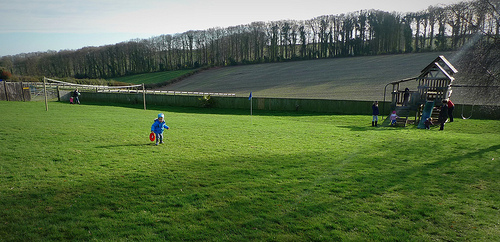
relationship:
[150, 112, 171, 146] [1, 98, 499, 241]
children on grass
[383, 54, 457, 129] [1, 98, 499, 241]
playground on grass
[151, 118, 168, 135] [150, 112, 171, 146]
jacket on children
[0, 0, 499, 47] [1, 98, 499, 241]
sky above grass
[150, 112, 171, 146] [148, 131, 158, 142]
children holding frisbee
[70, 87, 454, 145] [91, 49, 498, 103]
children near a large hill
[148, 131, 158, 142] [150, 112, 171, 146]
frisbee held by children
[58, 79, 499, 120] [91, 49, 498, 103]
fence near large hill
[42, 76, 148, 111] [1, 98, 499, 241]
volleyball net on grass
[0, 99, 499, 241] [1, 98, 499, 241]
shadow on grass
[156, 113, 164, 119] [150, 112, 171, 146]
hat on children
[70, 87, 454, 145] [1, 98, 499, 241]
children on grass